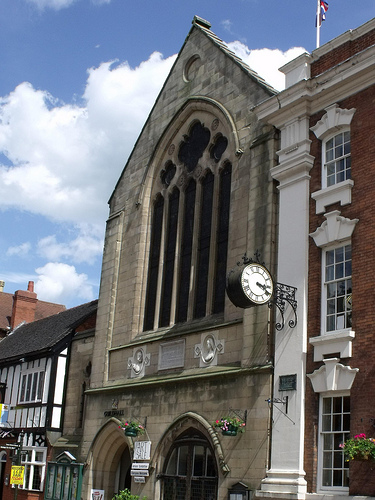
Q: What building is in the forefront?
A: A church.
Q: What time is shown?
A: 3:19.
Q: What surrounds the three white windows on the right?
A: Brick building.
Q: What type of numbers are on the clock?
A: Roman numerals.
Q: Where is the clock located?
A: Attached to building.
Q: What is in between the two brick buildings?
A: White column.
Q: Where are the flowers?
A: In pots hanging from building.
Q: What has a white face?
A: The clock.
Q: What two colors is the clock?
A: Black and white.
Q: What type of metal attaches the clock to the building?
A: Black scroll metal.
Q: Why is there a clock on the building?
A: For people to know the time.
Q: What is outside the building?
A: An outside clock on an old building.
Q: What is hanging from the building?
A: Plants hanging on the building.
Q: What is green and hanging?
A: Plants.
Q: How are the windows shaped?
A: The windows are arched.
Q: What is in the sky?
A: Blue sky with white clouds.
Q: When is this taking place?
A: Day time.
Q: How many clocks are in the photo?
A: One.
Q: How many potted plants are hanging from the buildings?
A: Three.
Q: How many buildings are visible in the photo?
A: Four.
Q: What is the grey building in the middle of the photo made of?
A: Stone.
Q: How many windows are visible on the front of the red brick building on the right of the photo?
A: Three.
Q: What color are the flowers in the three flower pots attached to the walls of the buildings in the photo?
A: Red.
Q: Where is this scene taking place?
A: At a church.